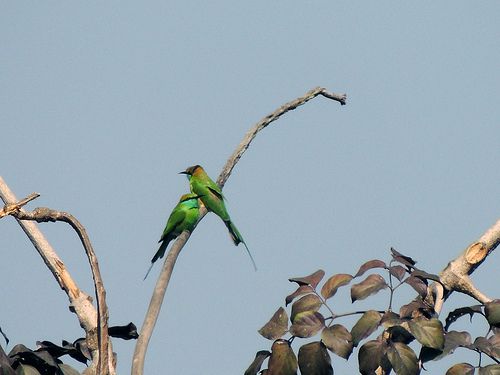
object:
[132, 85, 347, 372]
branch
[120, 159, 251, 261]
birds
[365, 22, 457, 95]
train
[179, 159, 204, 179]
head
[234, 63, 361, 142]
branch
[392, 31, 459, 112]
clouds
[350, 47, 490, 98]
sky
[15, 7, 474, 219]
sky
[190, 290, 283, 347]
clouds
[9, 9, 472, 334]
sky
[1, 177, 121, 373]
branches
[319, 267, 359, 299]
leaf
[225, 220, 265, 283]
feather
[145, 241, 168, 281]
feather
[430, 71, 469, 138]
no cloud????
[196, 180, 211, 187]
green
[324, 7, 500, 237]
sky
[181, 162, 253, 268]
right bird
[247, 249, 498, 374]
leaves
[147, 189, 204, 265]
bird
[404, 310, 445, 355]
leaf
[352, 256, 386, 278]
leaf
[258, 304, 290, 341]
leaf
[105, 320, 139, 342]
leaf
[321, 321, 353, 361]
leaf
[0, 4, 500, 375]
photo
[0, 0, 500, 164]
clouds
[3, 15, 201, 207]
sky